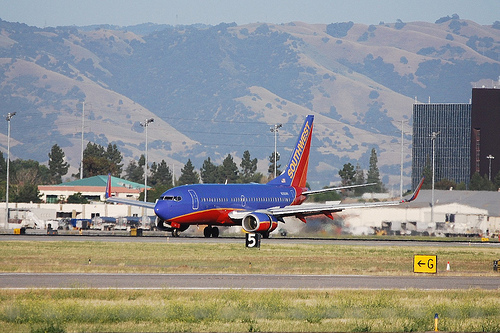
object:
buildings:
[409, 102, 472, 188]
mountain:
[0, 19, 490, 187]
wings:
[270, 177, 423, 219]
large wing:
[100, 178, 155, 212]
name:
[285, 120, 311, 177]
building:
[33, 172, 153, 199]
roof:
[58, 174, 150, 188]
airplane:
[109, 112, 423, 237]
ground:
[0, 237, 499, 247]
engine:
[239, 209, 278, 231]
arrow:
[417, 260, 427, 267]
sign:
[413, 254, 436, 274]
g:
[425, 257, 436, 270]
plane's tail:
[269, 114, 316, 188]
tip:
[408, 175, 429, 200]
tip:
[108, 172, 111, 176]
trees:
[43, 143, 69, 177]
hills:
[1, 60, 200, 175]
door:
[186, 189, 200, 210]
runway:
[0, 233, 498, 247]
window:
[178, 196, 181, 201]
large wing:
[265, 177, 427, 217]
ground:
[24, 243, 465, 269]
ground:
[12, 284, 494, 321]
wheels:
[203, 226, 211, 237]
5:
[243, 232, 259, 246]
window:
[201, 198, 203, 201]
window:
[253, 197, 255, 201]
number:
[242, 230, 257, 247]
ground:
[0, 244, 499, 305]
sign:
[244, 233, 261, 248]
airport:
[0, 174, 500, 333]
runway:
[3, 271, 493, 286]